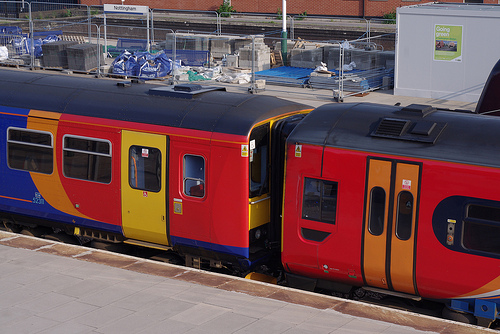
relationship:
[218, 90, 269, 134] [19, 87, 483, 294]
roof of train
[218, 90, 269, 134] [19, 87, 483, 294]
roof on train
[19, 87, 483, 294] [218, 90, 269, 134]
train of roof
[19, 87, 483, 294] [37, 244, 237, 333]
train on ground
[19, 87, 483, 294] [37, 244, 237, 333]
train near ground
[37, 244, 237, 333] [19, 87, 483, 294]
ground near train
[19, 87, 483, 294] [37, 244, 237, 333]
train by ground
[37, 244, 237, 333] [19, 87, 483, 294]
ground by train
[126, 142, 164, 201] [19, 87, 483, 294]
window on train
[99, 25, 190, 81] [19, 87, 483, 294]
bags are by train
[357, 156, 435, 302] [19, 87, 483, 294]
door on train